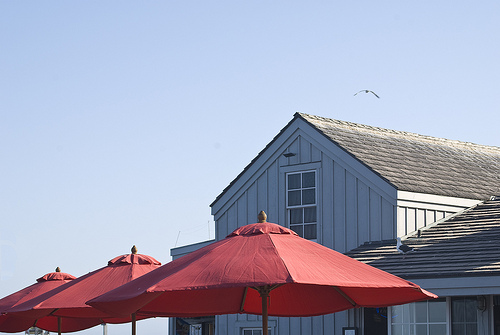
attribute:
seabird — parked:
[278, 147, 297, 158]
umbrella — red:
[85, 209, 443, 318]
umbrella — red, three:
[21, 259, 410, 317]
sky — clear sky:
[1, 4, 498, 281]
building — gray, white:
[187, 95, 498, 315]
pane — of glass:
[288, 177, 297, 189]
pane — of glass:
[302, 175, 314, 187]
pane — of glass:
[289, 193, 300, 203]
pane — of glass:
[305, 194, 315, 206]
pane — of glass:
[305, 212, 312, 220]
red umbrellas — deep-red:
[86, 210, 436, 332]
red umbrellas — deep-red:
[6, 244, 164, 322]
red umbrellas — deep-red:
[1, 265, 89, 334]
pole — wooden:
[248, 281, 278, 334]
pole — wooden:
[124, 303, 140, 334]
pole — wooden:
[51, 313, 67, 334]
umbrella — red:
[89, 214, 447, 325]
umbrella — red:
[0, 267, 79, 332]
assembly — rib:
[235, 279, 284, 299]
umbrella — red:
[5, 245, 175, 326]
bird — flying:
[349, 86, 379, 100]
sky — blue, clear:
[0, 5, 499, 334]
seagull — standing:
[394, 237, 415, 267]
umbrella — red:
[85, 210, 438, 333]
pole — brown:
[245, 283, 280, 333]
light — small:
[282, 147, 297, 160]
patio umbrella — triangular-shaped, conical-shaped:
[144, 212, 422, 317]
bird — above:
[351, 88, 380, 98]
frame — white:
[278, 159, 326, 248]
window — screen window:
[360, 303, 393, 333]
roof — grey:
[296, 110, 496, 203]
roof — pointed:
[150, 84, 430, 261]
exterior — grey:
[162, 84, 496, 220]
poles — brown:
[39, 309, 174, 331]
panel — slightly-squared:
[82, 235, 234, 305]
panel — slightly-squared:
[145, 235, 295, 294]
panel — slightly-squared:
[264, 232, 418, 289]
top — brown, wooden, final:
[254, 208, 265, 221]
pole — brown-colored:
[257, 291, 272, 331]